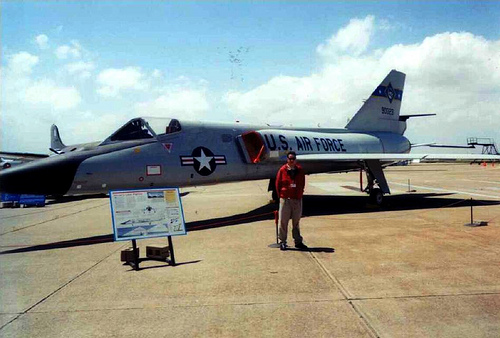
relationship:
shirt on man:
[271, 161, 308, 201] [273, 151, 308, 251]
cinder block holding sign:
[119, 244, 142, 266] [102, 182, 191, 240]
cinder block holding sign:
[142, 241, 172, 261] [102, 182, 191, 240]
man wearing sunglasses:
[273, 151, 308, 251] [283, 155, 297, 164]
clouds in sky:
[191, 47, 348, 130] [0, 1, 497, 160]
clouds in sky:
[3, 9, 496, 151] [0, 1, 497, 160]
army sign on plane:
[161, 140, 226, 177] [14, 63, 434, 206]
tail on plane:
[343, 52, 430, 147] [1, 61, 497, 236]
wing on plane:
[290, 138, 498, 171] [14, 63, 434, 206]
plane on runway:
[14, 63, 434, 206] [1, 160, 497, 334]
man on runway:
[273, 151, 308, 251] [1, 160, 497, 334]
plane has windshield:
[14, 63, 434, 206] [110, 114, 182, 142]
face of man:
[280, 149, 300, 169] [273, 151, 308, 251]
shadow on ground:
[284, 244, 332, 252] [1, 158, 498, 334]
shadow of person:
[266, 242, 332, 252] [258, 145, 316, 258]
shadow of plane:
[4, 190, 499, 260] [2, 68, 498, 200]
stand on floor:
[115, 237, 153, 281] [1, 151, 497, 335]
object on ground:
[459, 188, 495, 234] [1, 158, 498, 334]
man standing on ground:
[273, 151, 308, 251] [1, 158, 498, 334]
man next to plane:
[273, 151, 308, 251] [3, 37, 464, 249]